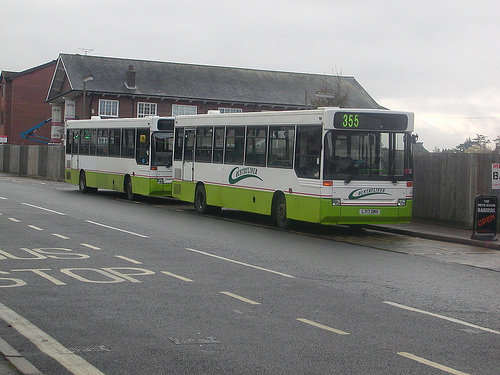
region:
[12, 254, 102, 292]
words on the street.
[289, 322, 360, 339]
white line on the street.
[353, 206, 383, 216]
license plate on the bus.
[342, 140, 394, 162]
windshield on the bus.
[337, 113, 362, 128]
number on the bus.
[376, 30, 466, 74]
clouds in the sky.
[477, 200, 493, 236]
words on the sign.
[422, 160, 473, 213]
fence made of wood.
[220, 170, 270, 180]
writing on the bus.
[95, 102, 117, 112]
window on the building.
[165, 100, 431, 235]
Green and white bus in the front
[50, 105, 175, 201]
Green and white bus parked in back of first bus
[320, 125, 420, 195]
Windshield of first bus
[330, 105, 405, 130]
First bus's number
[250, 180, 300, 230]
Front right wheel of front bus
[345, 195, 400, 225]
License plate on front of bus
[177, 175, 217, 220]
Right rear tire of bus in the front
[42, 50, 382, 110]
Roof of building in back of bus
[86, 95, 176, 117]
Windows of building in back of bus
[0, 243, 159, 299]
Information for buses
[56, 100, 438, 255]
Two buses parked on the side of the road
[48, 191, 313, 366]
White paint on the road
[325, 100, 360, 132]
Green numbering on bus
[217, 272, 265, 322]
White dotted line on pavement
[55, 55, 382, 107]
Roof on top of the building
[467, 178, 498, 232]
Sign on the side of the road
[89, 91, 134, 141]
Window on side of building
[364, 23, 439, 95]
The sky is full of clouds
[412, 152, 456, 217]
The fence is wooden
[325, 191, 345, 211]
Light in front of the bus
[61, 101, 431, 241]
bus on side of road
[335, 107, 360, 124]
number 355 on front of bus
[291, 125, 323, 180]
side window of bus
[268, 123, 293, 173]
side window of bus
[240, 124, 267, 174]
side window of bus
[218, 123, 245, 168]
side window of bus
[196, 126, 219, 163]
side window of bus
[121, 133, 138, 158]
side window of bus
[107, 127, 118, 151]
side window of bus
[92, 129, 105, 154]
side window of bus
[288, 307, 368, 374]
white line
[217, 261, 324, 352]
white line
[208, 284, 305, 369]
white line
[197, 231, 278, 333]
white line